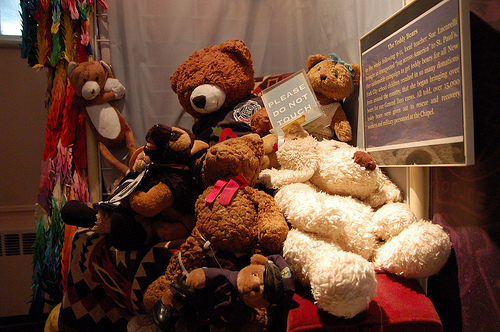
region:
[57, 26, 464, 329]
a pile of stuffed animals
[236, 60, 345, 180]
the sign says please do not touch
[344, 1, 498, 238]
a sign on the wall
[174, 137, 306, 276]
the bear has a pink bow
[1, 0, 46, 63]
a small portion of a window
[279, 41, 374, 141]
the bear has a blue headband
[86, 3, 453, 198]
the sheet behind the bears is white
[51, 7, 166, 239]
one bear is hanging on a pole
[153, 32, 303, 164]
the bear on top is big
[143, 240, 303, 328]
at the bottom is a police bear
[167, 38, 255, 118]
head of a big brown teddy bear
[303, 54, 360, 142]
teddy bear with a bow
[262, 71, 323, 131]
Please do not touch sign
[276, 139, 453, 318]
big white teddy bear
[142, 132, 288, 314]
teddy bear with a bow on its neck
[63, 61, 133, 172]
a teddy bear with long legs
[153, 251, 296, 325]
teddy bear wearing a hat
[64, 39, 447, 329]
a pile of teddy bears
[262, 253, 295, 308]
a teddy bear's hat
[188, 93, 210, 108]
a teddy bear's nose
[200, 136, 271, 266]
brown teddy bear with red bow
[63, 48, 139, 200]
brown teedy bear with white ears and belly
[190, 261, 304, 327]
brown teddy bear dressed as police officer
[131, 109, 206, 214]
two tone brown stuffed dog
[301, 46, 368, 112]
brown teddy bear with blue ribbon in hair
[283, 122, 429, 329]
cream stuffed dog with brown dogs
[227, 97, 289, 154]
badge on stuffed bears outfit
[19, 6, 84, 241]
length on colored ribbon hanging on pole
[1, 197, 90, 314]
wall heater attached to wall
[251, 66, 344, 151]
please do not touch sign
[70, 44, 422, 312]
a group of teddy bears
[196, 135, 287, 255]
teddy bear with red ribbon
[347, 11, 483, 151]
a plaque describing teddy bear display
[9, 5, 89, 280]
colorful strips of fabric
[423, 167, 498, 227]
words police written on fabric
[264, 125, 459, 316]
a light colored teddy bear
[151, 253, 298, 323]
a police officer teddy bear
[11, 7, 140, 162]
teddy bear hanging on post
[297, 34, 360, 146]
teddy bear with blue headband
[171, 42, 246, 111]
Brown teddy bear.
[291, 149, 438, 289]
White teddy bear.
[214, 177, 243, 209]
Teddy bear with red ribbon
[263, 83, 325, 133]
Please do not touch sign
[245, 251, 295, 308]
Brown bear wearing a hat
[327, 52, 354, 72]
Brown bear with a blue ribbon on head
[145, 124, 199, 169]
stuffed animal that black and brown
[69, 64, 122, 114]
A brown and white stuffed animal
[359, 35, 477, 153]
A sign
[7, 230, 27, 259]
air vents